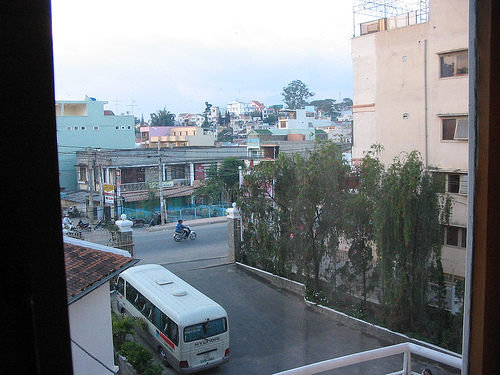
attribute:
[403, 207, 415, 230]
leaves — green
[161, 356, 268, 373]
lights — red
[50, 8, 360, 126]
sky — overcast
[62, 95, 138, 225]
building — large, blue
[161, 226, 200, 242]
coat — blue